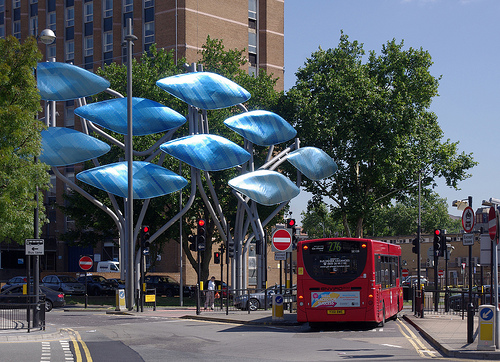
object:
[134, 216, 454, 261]
traffic lights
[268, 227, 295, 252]
sign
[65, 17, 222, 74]
windows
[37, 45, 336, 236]
structure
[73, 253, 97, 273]
sign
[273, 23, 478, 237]
tree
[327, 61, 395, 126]
leaves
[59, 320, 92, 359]
lines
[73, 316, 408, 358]
road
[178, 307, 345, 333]
shadow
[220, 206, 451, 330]
bus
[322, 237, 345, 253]
number 276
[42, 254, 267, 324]
vehicles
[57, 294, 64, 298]
red taillight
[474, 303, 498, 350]
white arrow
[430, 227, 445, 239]
red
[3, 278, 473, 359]
ground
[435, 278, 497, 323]
sign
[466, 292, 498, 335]
down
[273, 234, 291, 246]
stripe